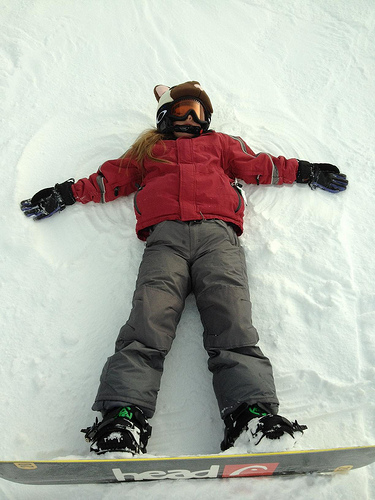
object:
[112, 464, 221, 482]
word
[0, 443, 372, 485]
snowboard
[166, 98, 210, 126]
goggles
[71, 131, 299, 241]
jacket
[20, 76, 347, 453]
girl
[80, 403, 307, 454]
shoes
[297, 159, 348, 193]
glove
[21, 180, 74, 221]
glove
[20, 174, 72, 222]
hand